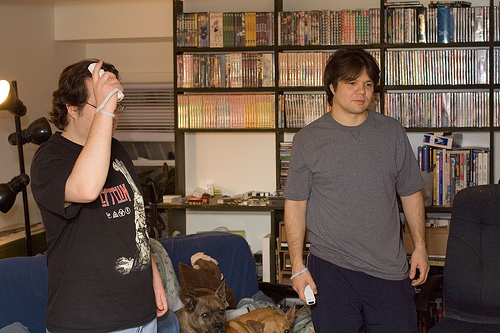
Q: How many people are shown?
A: 2.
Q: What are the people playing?
A: WII.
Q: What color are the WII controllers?
A: White.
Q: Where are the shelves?
A: Wall.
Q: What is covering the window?
A: Blinds.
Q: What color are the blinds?
A: White.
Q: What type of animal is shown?
A: Dog.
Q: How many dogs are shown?
A: 2.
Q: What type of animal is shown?
A: Dogs.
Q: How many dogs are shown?
A: 2.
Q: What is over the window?
A: Blinds.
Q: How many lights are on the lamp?
A: 3.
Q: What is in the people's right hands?
A: WII controllers.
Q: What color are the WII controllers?
A: White.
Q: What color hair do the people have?
A: Brown.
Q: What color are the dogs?
A: Brown and tan.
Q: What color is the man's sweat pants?
A: Dark blue.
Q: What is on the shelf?
A: Books.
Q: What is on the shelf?
A: DVDs.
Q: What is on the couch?
A: Two dogs.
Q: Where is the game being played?
A: Inside a house.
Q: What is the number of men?
A: Two.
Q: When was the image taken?
A: At night.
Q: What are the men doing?
A: Playing Wii.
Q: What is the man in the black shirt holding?
A: Wii controller.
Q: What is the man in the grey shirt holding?
A: Wii controller.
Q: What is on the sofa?
A: Two dogs.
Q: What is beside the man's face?
A: Wii controller.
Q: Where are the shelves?
A: Behind the players and the furniture.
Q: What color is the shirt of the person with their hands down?
A: Grey.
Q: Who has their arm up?
A: A player with a black top and blue jeans and glasses on.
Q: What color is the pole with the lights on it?
A: Black.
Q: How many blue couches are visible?
A: Just one.